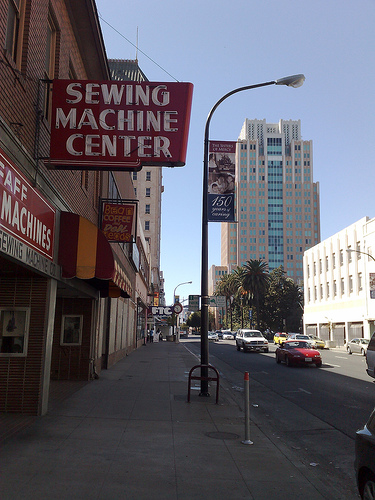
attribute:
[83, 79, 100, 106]
letter — white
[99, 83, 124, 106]
letter — white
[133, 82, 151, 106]
letter — white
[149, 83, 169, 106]
letter — white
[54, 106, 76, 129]
letter — white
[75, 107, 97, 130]
letter — white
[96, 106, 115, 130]
letter — white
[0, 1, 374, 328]
sky — blue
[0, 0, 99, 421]
building — brick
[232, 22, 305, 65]
sky —  blue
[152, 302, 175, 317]
sign — distant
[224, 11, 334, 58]
sky — clear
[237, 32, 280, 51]
clouds — white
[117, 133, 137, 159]
letter — white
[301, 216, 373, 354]
building — white 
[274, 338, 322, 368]
car — red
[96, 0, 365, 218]
sky — blue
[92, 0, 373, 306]
sky — blue,  blue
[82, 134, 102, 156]
letter — white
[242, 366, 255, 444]
pole — short 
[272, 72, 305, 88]
light — off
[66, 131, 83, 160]
letter — white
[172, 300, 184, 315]
clock — red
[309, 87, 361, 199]
sky — blue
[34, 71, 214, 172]
sign — red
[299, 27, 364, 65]
sky — blue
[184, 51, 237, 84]
clouds — white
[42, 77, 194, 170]
sign — red and white, white, red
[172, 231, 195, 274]
clouds — white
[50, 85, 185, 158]
sign — red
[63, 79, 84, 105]
letter — white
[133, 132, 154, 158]
letter — white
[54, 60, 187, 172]
sign — red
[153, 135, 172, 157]
letter — white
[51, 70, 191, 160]
letter — white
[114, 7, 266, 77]
clouds — white 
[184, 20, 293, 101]
clouds — white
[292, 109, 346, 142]
clouds — white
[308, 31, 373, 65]
clouds — white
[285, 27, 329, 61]
clouds — white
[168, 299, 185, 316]
face — white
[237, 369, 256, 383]
top — orange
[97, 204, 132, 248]
coffee — orange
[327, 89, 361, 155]
clouds — white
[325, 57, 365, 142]
clouds — white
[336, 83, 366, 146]
clouds — white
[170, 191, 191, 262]
clouds — white